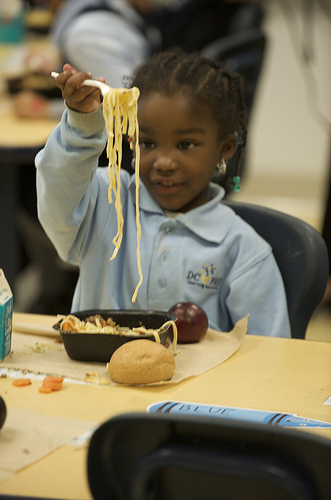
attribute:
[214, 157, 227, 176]
earring — small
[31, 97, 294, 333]
shirt — blue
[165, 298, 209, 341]
apple — dark red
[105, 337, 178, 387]
bun — wheat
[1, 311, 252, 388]
napkin — brown